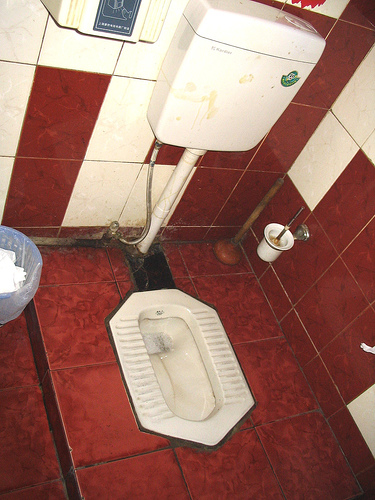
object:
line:
[119, 139, 164, 247]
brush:
[269, 206, 302, 248]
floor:
[0, 236, 363, 499]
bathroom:
[0, 0, 375, 498]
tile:
[311, 147, 375, 255]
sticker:
[281, 71, 300, 87]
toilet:
[109, 287, 256, 445]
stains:
[237, 72, 254, 87]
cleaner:
[271, 236, 285, 244]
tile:
[286, 109, 359, 213]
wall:
[241, 47, 374, 493]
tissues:
[0, 249, 27, 291]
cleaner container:
[255, 221, 295, 264]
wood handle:
[233, 177, 284, 243]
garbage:
[0, 245, 29, 292]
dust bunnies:
[115, 222, 131, 233]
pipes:
[115, 140, 162, 246]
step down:
[18, 298, 83, 499]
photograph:
[0, 2, 375, 499]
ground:
[0, 239, 363, 498]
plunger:
[212, 239, 242, 263]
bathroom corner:
[209, 225, 256, 275]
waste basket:
[0, 223, 43, 327]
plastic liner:
[0, 225, 43, 323]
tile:
[49, 359, 173, 467]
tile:
[14, 64, 112, 160]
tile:
[84, 76, 154, 171]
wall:
[0, 1, 375, 239]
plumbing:
[107, 143, 162, 246]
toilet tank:
[145, 1, 328, 153]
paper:
[0, 246, 29, 293]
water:
[144, 330, 173, 357]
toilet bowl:
[109, 289, 256, 446]